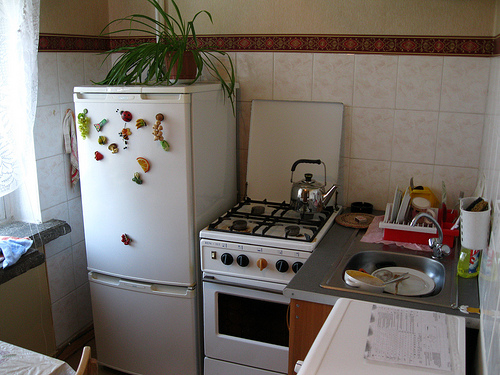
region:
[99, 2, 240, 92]
A green potted plant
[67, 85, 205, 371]
A white refridgerator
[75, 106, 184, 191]
Magnets on the front of a white refridgerator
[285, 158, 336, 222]
A silver teakettle with a black handle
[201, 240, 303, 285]
Knobs on the front of a stove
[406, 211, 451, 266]
A silver faucet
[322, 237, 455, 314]
Dirty dishes in a sink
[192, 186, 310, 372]
A white gas stove with different colored knobs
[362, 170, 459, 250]
Clean dishes in a red dish holder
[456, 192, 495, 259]
a sponge that is in a white holder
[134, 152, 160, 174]
an orange slice magnet on the refrigerator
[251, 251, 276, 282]
a brown knob on the stove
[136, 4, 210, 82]
a green plant in a terra cotta pot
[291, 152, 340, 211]
a silver tea kettle with a black handle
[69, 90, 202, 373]
a white refrigerator with colorful magnets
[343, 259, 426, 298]
dirty dishes in a stainless steel sink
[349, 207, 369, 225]
a book of matches on a wicker mat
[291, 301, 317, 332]
a wooden cabinet under the sink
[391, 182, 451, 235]
dishes on plastic strainer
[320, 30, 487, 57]
floral border on the wall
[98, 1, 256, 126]
green plant in pot on top of fridge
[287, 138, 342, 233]
stainless steel kettle on stove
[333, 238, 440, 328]
dirty dishes in sink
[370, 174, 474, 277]
red and white dish drainer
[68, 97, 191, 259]
multi colored magnets on front of fridge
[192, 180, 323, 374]
white gas stove in kitchen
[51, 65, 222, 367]
refrigerator freezer combo in kitchen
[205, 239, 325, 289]
knobs on front of stove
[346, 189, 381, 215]
black ash tray sitting on counter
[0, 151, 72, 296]
window cell with light coming through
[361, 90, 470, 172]
this is a wall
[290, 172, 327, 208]
this is a kettle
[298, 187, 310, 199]
the kettle is shinny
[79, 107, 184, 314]
this is a refrigerator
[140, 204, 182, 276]
the refrigerator is white in color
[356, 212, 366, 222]
this is a match box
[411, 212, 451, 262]
this is a tap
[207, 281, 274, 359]
this is an oven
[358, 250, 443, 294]
this is a sink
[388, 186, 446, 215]
these are the utensils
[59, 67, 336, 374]
white refrigerator and white stove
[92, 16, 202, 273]
plant on top of refrigerator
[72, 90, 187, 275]
magnets on refrigerator door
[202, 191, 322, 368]
stove with gas burners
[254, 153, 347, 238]
tea kettle on stove top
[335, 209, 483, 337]
dirty dishes in sink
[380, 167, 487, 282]
clean dishes next to sink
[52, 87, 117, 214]
towel hanging on wall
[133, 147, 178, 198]
orange slice magnet on refrigerator door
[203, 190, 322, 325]
stove with four black knobs